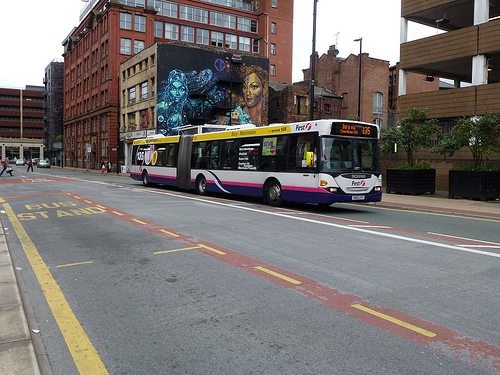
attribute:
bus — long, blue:
[129, 118, 382, 208]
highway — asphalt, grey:
[1, 161, 499, 374]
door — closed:
[360, 137, 376, 171]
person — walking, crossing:
[26, 157, 34, 172]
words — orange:
[339, 122, 371, 134]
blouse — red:
[28, 159, 33, 166]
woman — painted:
[234, 63, 268, 126]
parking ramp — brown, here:
[398, 0, 499, 159]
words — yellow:
[16, 200, 106, 221]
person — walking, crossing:
[0, 155, 14, 178]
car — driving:
[36, 158, 50, 169]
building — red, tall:
[63, 1, 293, 174]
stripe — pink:
[190, 177, 332, 193]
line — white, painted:
[14, 167, 499, 258]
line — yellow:
[0, 196, 111, 374]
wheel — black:
[195, 174, 210, 196]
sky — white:
[0, 0, 472, 90]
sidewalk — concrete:
[365, 192, 500, 220]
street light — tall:
[353, 37, 363, 121]